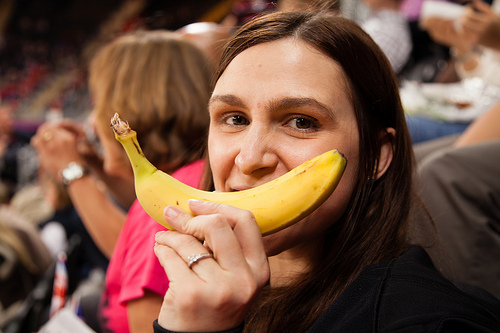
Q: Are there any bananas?
A: Yes, there is a banana.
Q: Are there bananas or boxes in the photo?
A: Yes, there is a banana.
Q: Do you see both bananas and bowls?
A: No, there is a banana but no bowls.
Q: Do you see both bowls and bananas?
A: No, there is a banana but no bowls.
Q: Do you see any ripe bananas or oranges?
A: Yes, there is a ripe banana.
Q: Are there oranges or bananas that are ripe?
A: Yes, the banana is ripe.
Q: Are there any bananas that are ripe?
A: Yes, there is a ripe banana.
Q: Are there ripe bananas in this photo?
A: Yes, there is a ripe banana.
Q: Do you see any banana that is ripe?
A: Yes, there is a banana that is ripe.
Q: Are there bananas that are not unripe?
A: Yes, there is an ripe banana.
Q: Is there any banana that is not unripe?
A: Yes, there is an ripe banana.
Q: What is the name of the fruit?
A: The fruit is a banana.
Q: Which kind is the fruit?
A: The fruit is a banana.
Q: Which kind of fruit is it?
A: The fruit is a banana.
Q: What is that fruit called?
A: This is a banana.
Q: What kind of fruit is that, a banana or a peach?
A: This is a banana.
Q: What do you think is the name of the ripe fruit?
A: The fruit is a banana.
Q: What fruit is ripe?
A: The fruit is a banana.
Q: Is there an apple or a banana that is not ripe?
A: No, there is a banana but it is ripe.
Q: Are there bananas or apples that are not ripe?
A: No, there is a banana but it is ripe.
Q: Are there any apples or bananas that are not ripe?
A: No, there is a banana but it is ripe.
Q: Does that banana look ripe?
A: Yes, the banana is ripe.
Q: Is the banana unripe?
A: No, the banana is ripe.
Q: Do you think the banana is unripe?
A: No, the banana is ripe.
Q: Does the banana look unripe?
A: No, the banana is ripe.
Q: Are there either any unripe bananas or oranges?
A: No, there is a banana but it is ripe.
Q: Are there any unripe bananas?
A: No, there is a banana but it is ripe.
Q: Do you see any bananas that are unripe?
A: No, there is a banana but it is ripe.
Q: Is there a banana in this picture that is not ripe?
A: No, there is a banana but it is ripe.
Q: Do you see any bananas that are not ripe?
A: No, there is a banana but it is ripe.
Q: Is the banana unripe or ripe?
A: The banana is ripe.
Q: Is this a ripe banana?
A: Yes, this is a ripe banana.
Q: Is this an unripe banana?
A: No, this is a ripe banana.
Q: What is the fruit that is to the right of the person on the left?
A: The fruit is a banana.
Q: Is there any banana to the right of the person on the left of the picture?
A: Yes, there is a banana to the right of the person.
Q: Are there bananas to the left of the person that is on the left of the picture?
A: No, the banana is to the right of the person.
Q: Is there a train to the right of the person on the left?
A: No, there is a banana to the right of the person.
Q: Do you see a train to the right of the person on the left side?
A: No, there is a banana to the right of the person.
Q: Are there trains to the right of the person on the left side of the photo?
A: No, there is a banana to the right of the person.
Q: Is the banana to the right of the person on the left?
A: Yes, the banana is to the right of the person.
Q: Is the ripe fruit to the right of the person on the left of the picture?
A: Yes, the banana is to the right of the person.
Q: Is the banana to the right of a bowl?
A: No, the banana is to the right of the person.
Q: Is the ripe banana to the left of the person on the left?
A: No, the banana is to the right of the person.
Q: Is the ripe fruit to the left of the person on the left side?
A: No, the banana is to the right of the person.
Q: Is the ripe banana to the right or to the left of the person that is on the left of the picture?
A: The banana is to the right of the person.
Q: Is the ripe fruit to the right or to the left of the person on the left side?
A: The banana is to the right of the person.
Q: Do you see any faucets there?
A: No, there are no faucets.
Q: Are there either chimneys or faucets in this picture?
A: No, there are no faucets or chimneys.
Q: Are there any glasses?
A: No, there are no glasses.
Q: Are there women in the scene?
A: Yes, there is a woman.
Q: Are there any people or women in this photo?
A: Yes, there is a woman.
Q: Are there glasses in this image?
A: No, there are no glasses.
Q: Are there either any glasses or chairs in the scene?
A: No, there are no glasses or chairs.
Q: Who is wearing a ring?
A: The woman is wearing a ring.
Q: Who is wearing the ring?
A: The woman is wearing a ring.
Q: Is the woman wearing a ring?
A: Yes, the woman is wearing a ring.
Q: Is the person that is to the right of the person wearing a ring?
A: Yes, the woman is wearing a ring.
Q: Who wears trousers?
A: The woman wears trousers.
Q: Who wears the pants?
A: The woman wears trousers.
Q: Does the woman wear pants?
A: Yes, the woman wears pants.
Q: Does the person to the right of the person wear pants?
A: Yes, the woman wears pants.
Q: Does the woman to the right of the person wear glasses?
A: No, the woman wears pants.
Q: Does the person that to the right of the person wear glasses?
A: No, the woman wears pants.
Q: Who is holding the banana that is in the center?
A: The woman is holding the banana.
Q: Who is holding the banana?
A: The woman is holding the banana.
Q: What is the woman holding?
A: The woman is holding the banana.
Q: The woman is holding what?
A: The woman is holding the banana.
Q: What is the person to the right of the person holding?
A: The woman is holding the banana.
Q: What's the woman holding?
A: The woman is holding the banana.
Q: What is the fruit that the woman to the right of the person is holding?
A: The fruit is a banana.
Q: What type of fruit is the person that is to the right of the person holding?
A: The woman is holding the banana.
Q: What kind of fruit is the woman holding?
A: The woman is holding the banana.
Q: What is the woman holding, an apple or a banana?
A: The woman is holding a banana.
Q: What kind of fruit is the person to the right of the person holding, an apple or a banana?
A: The woman is holding a banana.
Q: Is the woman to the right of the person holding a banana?
A: Yes, the woman is holding a banana.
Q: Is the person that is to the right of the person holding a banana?
A: Yes, the woman is holding a banana.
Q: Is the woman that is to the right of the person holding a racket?
A: No, the woman is holding a banana.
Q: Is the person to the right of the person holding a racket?
A: No, the woman is holding a banana.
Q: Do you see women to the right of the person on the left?
A: Yes, there is a woman to the right of the person.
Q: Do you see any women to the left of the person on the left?
A: No, the woman is to the right of the person.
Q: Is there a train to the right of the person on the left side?
A: No, there is a woman to the right of the person.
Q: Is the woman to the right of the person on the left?
A: Yes, the woman is to the right of the person.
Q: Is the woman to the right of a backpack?
A: No, the woman is to the right of the person.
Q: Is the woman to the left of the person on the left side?
A: No, the woman is to the right of the person.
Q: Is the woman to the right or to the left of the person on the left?
A: The woman is to the right of the person.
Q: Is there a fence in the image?
A: No, there are no fences.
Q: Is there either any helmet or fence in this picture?
A: No, there are no fences or helmets.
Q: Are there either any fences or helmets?
A: No, there are no fences or helmets.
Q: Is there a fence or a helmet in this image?
A: No, there are no fences or helmets.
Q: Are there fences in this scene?
A: No, there are no fences.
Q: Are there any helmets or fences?
A: No, there are no fences or helmets.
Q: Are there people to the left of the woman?
A: Yes, there is a person to the left of the woman.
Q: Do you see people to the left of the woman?
A: Yes, there is a person to the left of the woman.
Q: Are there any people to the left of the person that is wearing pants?
A: Yes, there is a person to the left of the woman.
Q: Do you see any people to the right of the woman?
A: No, the person is to the left of the woman.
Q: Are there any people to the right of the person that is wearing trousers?
A: No, the person is to the left of the woman.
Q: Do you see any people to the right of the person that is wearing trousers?
A: No, the person is to the left of the woman.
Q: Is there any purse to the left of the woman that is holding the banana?
A: No, there is a person to the left of the woman.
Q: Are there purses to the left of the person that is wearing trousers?
A: No, there is a person to the left of the woman.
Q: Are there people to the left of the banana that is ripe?
A: Yes, there is a person to the left of the banana.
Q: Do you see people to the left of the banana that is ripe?
A: Yes, there is a person to the left of the banana.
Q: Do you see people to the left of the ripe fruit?
A: Yes, there is a person to the left of the banana.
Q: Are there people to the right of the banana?
A: No, the person is to the left of the banana.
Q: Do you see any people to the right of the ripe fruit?
A: No, the person is to the left of the banana.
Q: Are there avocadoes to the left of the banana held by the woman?
A: No, there is a person to the left of the banana.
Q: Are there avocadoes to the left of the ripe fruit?
A: No, there is a person to the left of the banana.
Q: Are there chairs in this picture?
A: No, there are no chairs.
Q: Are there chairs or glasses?
A: No, there are no chairs or glasses.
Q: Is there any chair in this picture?
A: No, there are no chairs.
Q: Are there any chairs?
A: No, there are no chairs.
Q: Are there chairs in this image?
A: No, there are no chairs.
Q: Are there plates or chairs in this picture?
A: No, there are no chairs or plates.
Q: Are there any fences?
A: No, there are no fences.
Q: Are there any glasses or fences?
A: No, there are no fences or glasses.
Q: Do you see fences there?
A: No, there are no fences.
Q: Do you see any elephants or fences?
A: No, there are no fences or elephants.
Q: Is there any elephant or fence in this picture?
A: No, there are no fences or elephants.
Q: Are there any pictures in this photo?
A: No, there are no pictures.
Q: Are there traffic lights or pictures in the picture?
A: No, there are no pictures or traffic lights.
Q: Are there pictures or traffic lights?
A: No, there are no pictures or traffic lights.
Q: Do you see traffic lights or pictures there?
A: No, there are no pictures or traffic lights.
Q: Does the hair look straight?
A: Yes, the hair is straight.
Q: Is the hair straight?
A: Yes, the hair is straight.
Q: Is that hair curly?
A: No, the hair is straight.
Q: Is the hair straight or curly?
A: The hair is straight.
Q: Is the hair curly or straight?
A: The hair is straight.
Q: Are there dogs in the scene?
A: No, there are no dogs.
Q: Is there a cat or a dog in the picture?
A: No, there are no dogs or cats.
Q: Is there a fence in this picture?
A: No, there are no fences.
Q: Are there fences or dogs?
A: No, there are no fences or dogs.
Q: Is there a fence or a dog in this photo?
A: No, there are no fences or dogs.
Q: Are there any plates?
A: No, there are no plates.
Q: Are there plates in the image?
A: No, there are no plates.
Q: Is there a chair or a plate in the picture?
A: No, there are no plates or chairs.